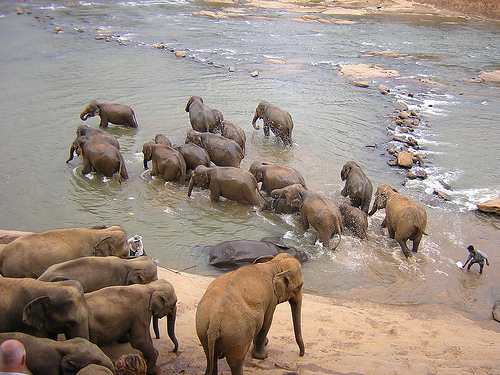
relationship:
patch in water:
[340, 62, 402, 81] [0, 0, 499, 335]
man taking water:
[462, 244, 490, 276] [0, 0, 499, 335]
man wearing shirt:
[462, 244, 490, 276] [465, 249, 490, 262]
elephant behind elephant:
[270, 182, 345, 253] [187, 164, 270, 207]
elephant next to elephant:
[338, 202, 370, 243] [270, 182, 345, 253]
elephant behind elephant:
[369, 184, 431, 262] [340, 160, 375, 215]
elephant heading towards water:
[195, 251, 306, 374] [0, 0, 499, 335]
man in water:
[128, 234, 149, 258] [0, 0, 499, 335]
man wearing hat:
[128, 234, 149, 258] [132, 234, 144, 244]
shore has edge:
[0, 227, 499, 373] [1, 227, 500, 337]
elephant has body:
[80, 99, 138, 130] [102, 102, 134, 125]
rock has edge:
[396, 150, 416, 171] [395, 151, 402, 168]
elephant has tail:
[270, 182, 345, 253] [331, 230, 342, 252]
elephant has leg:
[195, 251, 306, 374] [250, 297, 278, 361]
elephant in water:
[80, 99, 138, 130] [0, 0, 499, 335]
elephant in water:
[187, 164, 270, 207] [0, 0, 499, 335]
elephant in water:
[369, 184, 431, 262] [0, 0, 499, 335]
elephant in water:
[340, 160, 375, 215] [0, 0, 499, 335]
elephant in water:
[338, 202, 370, 243] [0, 0, 499, 335]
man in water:
[462, 244, 490, 276] [0, 0, 499, 335]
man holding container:
[462, 244, 490, 276] [455, 260, 465, 270]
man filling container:
[462, 244, 490, 276] [455, 260, 465, 270]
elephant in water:
[209, 237, 309, 269] [0, 0, 499, 335]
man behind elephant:
[462, 244, 490, 276] [369, 184, 431, 262]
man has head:
[462, 244, 490, 276] [467, 245, 475, 256]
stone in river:
[173, 50, 188, 59] [0, 0, 499, 335]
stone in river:
[15, 6, 26, 16] [0, 0, 499, 335]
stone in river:
[53, 26, 63, 33] [0, 0, 499, 335]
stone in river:
[228, 65, 236, 73] [0, 0, 499, 335]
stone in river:
[250, 69, 260, 77] [0, 0, 499, 335]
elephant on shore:
[195, 251, 306, 374] [0, 227, 499, 373]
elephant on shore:
[0, 224, 130, 278] [0, 227, 499, 373]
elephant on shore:
[37, 255, 160, 294] [0, 227, 499, 373]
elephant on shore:
[82, 278, 179, 374] [0, 227, 499, 373]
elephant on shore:
[0, 276, 90, 342] [0, 227, 499, 373]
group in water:
[67, 95, 431, 273] [0, 0, 499, 335]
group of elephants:
[67, 95, 431, 273] [1, 95, 430, 374]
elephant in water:
[270, 182, 345, 253] [0, 0, 499, 335]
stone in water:
[15, 6, 26, 16] [0, 0, 499, 335]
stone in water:
[53, 26, 63, 33] [0, 0, 499, 335]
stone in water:
[173, 50, 188, 59] [0, 0, 499, 335]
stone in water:
[228, 65, 236, 73] [0, 0, 499, 335]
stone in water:
[250, 69, 260, 77] [0, 0, 499, 335]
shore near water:
[0, 227, 499, 373] [0, 0, 499, 335]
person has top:
[113, 352, 149, 374] [114, 352, 148, 365]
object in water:
[415, 54, 441, 61] [0, 0, 499, 335]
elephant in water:
[251, 99, 295, 148] [0, 0, 499, 335]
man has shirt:
[462, 244, 490, 276] [465, 249, 490, 262]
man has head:
[1, 338, 27, 374] [1, 338, 27, 374]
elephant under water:
[209, 237, 309, 269] [0, 0, 499, 335]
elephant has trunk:
[195, 251, 306, 374] [288, 293, 306, 357]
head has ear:
[19, 278, 90, 335] [20, 293, 51, 332]